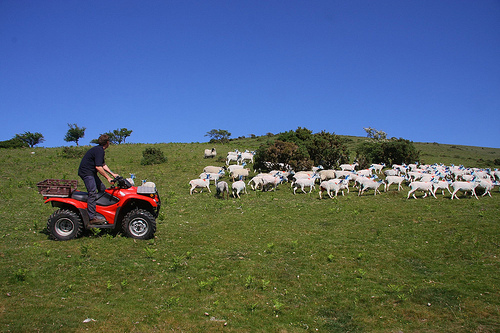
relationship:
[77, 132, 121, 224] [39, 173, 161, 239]
man riding wheeler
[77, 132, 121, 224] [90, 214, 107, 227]
man wearing boot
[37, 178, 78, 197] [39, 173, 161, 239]
basket on top of wheeler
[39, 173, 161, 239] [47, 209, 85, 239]
wheeler has wheel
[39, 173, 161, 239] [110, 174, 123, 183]
wheeler has steering wheel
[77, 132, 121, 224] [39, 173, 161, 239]
man standing on wheeler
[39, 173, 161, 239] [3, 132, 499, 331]
wheeler on top of hill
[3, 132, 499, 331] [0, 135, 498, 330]
hill has grass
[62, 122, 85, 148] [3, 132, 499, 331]
tree on top of hill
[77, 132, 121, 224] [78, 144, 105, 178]
man has shirt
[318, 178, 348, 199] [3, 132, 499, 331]
sheep on top of hill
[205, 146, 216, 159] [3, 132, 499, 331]
sheep on top of hill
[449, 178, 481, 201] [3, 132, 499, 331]
sheep on top of hill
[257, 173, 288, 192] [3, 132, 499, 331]
sheep on top of hill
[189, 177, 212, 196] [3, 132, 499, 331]
sheep on top of hill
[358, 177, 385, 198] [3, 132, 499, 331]
sheep on top of hill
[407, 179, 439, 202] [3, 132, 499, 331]
sheep on top of hill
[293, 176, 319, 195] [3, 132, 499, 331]
sheep on top of hill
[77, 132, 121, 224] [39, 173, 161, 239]
man driving wheeler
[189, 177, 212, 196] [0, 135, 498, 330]
sheep walking on grass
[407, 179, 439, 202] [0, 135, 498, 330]
sheep standing on grass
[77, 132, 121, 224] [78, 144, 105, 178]
man wearing shirt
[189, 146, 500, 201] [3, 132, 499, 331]
cattle on top of hill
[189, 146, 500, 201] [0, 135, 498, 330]
cattle grazing grass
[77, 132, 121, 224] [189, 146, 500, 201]
man herding cattle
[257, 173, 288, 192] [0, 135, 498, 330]
sheep eating grass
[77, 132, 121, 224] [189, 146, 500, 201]
man watching over cattle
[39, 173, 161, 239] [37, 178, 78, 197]
wheeler has basket